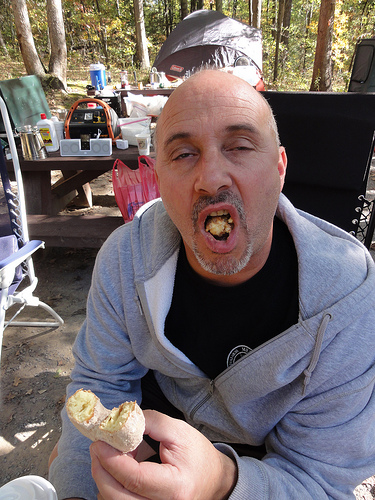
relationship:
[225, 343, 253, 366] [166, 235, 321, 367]
logo on black shirt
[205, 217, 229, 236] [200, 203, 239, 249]
donut in mouth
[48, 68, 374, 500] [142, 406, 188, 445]
man has thumb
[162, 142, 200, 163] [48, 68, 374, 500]
right eye of man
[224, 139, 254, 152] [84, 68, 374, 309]
left eye of man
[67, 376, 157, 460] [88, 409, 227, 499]
donut in hand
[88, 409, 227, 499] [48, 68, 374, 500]
hand of man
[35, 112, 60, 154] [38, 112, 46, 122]
bottle with cap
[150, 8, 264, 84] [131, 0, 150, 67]
camping tent between tree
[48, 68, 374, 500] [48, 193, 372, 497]
man wearing jacket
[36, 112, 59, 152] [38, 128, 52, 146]
bottle with yellow label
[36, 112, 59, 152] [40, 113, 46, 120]
bottle with cap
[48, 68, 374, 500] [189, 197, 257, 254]
man with mouth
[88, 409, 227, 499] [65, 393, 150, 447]
hand holding donut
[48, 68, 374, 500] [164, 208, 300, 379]
man wearing black shirt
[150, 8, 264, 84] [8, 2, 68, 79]
camping tent surrounded by tree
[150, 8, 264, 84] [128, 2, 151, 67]
camping tent surrounded by tree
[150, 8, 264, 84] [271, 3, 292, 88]
camping tent surrounded by tree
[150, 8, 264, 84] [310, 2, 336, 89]
camping tent surrounded by tree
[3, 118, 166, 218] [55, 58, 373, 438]
table behind man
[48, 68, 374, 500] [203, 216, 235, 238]
man with food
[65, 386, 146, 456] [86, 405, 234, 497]
donut in hand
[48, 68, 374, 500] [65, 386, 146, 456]
man eating donut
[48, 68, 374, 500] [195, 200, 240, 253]
man with open mouth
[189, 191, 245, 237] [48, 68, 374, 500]
mustache of a man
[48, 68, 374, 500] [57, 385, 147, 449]
man eating a donut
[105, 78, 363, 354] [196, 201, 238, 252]
man opens h mouth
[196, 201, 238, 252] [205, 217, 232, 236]
mouth full of donut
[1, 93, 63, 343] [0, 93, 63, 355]
base of a chair